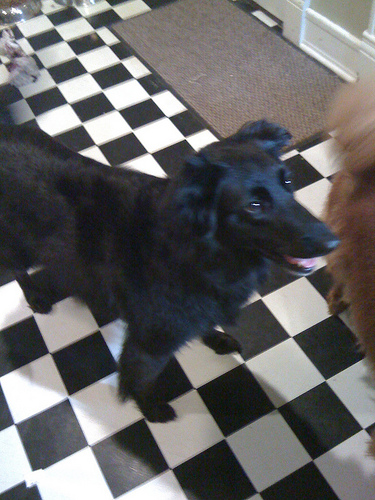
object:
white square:
[265, 277, 332, 340]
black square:
[290, 310, 367, 382]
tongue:
[286, 251, 352, 275]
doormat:
[111, 2, 371, 161]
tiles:
[50, 50, 179, 163]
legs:
[123, 286, 225, 399]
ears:
[232, 114, 292, 152]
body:
[0, 122, 245, 344]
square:
[117, 98, 168, 130]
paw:
[117, 385, 176, 424]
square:
[278, 379, 363, 463]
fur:
[81, 189, 137, 259]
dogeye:
[281, 175, 291, 187]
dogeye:
[245, 196, 264, 211]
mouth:
[275, 248, 333, 278]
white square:
[229, 412, 322, 489]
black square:
[196, 355, 279, 434]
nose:
[315, 223, 343, 256]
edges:
[110, 26, 181, 106]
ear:
[173, 157, 229, 239]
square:
[143, 386, 230, 470]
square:
[195, 360, 274, 438]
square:
[243, 337, 325, 408]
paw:
[209, 330, 244, 355]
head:
[168, 117, 343, 283]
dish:
[0, 0, 43, 26]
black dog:
[0, 121, 338, 423]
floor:
[99, 0, 359, 162]